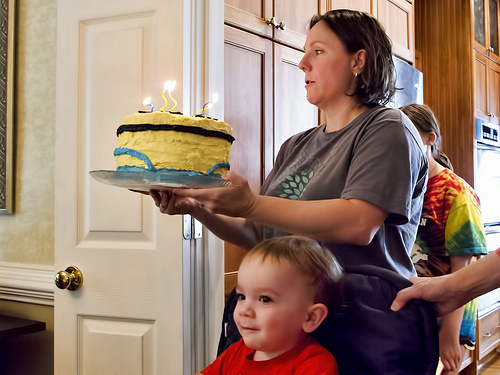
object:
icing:
[113, 103, 230, 177]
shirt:
[195, 337, 338, 375]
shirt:
[259, 106, 436, 296]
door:
[225, 24, 274, 274]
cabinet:
[222, 0, 273, 41]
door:
[51, 0, 190, 375]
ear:
[350, 47, 369, 78]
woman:
[132, 8, 426, 374]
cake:
[110, 108, 240, 177]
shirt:
[416, 161, 488, 351]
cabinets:
[413, 0, 473, 190]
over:
[472, 115, 499, 129]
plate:
[86, 162, 231, 193]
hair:
[308, 10, 398, 110]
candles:
[140, 96, 158, 113]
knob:
[56, 265, 86, 294]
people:
[397, 100, 483, 375]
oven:
[472, 117, 499, 149]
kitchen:
[169, 0, 500, 375]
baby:
[190, 233, 349, 374]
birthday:
[89, 10, 500, 374]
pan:
[86, 167, 246, 193]